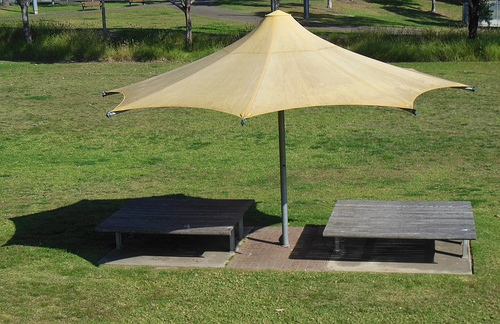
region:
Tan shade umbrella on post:
[99, 7, 479, 248]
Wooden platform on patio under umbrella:
[321, 197, 479, 257]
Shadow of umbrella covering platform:
[2, 191, 302, 268]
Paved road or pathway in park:
[36, 4, 498, 34]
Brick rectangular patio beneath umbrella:
[226, 223, 335, 271]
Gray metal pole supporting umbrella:
[276, 109, 290, 248]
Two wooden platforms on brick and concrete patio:
[95, 195, 477, 277]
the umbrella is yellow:
[101, 8, 475, 121]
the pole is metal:
[278, 109, 288, 247]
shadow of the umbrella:
[4, 191, 299, 265]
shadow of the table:
[288, 224, 461, 264]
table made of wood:
[321, 196, 473, 258]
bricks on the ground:
[227, 226, 332, 273]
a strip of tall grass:
[2, 24, 498, 61]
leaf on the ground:
[275, 308, 285, 313]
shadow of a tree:
[369, 0, 462, 26]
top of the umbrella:
[265, 7, 288, 14]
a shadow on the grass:
[41, 208, 78, 240]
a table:
[340, 202, 467, 233]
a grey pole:
[276, 120, 297, 251]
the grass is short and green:
[54, 115, 118, 169]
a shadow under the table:
[307, 235, 329, 256]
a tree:
[181, 8, 201, 55]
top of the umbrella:
[261, 9, 291, 26]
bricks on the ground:
[261, 243, 282, 265]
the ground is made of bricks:
[255, 245, 280, 267]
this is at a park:
[11, 10, 498, 310]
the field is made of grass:
[51, 127, 493, 322]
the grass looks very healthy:
[38, 121, 276, 175]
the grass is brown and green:
[15, 131, 196, 188]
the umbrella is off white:
[138, 24, 496, 134]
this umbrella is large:
[110, 11, 404, 125]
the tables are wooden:
[121, 177, 471, 261]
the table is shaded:
[32, 191, 213, 269]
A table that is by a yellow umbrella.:
[323, 197, 477, 261]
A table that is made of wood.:
[322, 193, 478, 262]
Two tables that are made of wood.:
[105, 192, 479, 257]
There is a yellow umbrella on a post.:
[88, 2, 482, 122]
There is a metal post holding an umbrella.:
[268, 107, 300, 249]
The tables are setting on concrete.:
[96, 192, 478, 277]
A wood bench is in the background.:
[74, 0, 109, 9]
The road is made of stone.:
[169, 1, 485, 43]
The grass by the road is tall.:
[0, 23, 499, 65]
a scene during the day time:
[7, 3, 495, 321]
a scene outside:
[5, 2, 499, 322]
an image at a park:
[9, 6, 496, 320]